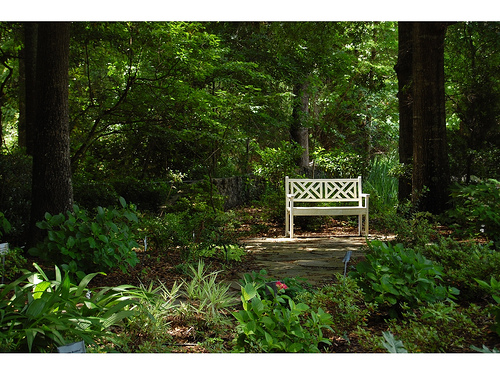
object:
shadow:
[255, 240, 352, 282]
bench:
[284, 175, 370, 239]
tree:
[365, 23, 377, 173]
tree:
[445, 21, 498, 186]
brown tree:
[410, 21, 450, 223]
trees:
[230, 21, 384, 174]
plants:
[0, 234, 500, 353]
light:
[241, 230, 397, 253]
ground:
[11, 207, 496, 339]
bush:
[36, 185, 183, 270]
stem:
[343, 263, 347, 289]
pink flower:
[275, 281, 288, 290]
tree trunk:
[28, 46, 75, 208]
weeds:
[299, 270, 379, 335]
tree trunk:
[411, 22, 445, 184]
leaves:
[466, 275, 500, 305]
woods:
[2, 23, 495, 351]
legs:
[290, 216, 293, 239]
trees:
[2, 21, 500, 228]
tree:
[25, 22, 73, 250]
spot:
[236, 229, 396, 255]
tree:
[407, 23, 450, 215]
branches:
[71, 27, 273, 172]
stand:
[285, 208, 369, 239]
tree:
[68, 21, 295, 196]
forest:
[7, 21, 494, 355]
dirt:
[239, 219, 369, 282]